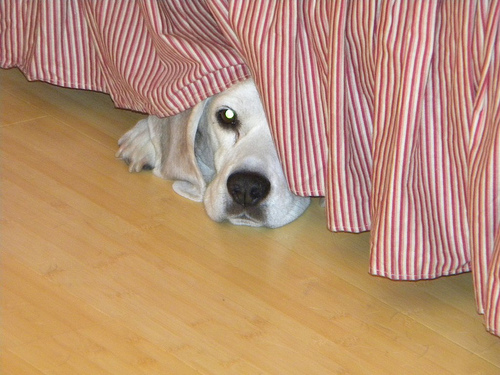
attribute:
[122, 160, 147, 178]
toenail — white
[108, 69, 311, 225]
dog — white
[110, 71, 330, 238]
dog — white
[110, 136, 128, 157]
toenail — white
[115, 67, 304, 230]
dog — white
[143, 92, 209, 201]
ear — large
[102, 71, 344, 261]
dog — white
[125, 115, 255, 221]
ear — folded, laying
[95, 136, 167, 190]
nails — white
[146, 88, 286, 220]
dog — peeking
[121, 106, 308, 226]
puppy — white, laying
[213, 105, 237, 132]
eye — brown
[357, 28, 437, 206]
candy stripe — white, red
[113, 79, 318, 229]
pooch — peeking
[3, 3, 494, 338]
cover — candy striped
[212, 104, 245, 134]
eye — glistening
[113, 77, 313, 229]
puppy — white, peeping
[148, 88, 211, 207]
ear — long, floppy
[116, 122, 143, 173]
claws — small, little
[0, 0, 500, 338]
tablecloth — red and white striped, red and white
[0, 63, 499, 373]
floor — wood, wooden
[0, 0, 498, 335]
bed skirt — red, white, red and white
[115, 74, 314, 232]
dog — white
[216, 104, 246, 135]
eye — brown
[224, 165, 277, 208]
nose — black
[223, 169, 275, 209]
nose — black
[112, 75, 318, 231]
canine — white